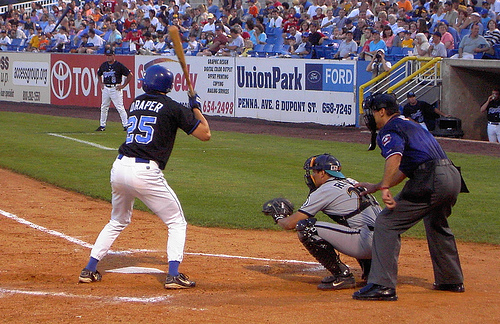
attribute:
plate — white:
[102, 259, 169, 282]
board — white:
[277, 31, 368, 135]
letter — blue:
[290, 74, 300, 91]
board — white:
[233, 55, 358, 126]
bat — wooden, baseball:
[147, 22, 227, 111]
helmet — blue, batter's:
[141, 64, 173, 94]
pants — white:
[89, 150, 201, 264]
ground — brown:
[2, 162, 499, 322]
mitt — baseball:
[256, 188, 293, 228]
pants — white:
[418, 122, 429, 132]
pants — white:
[487, 122, 499, 142]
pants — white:
[89, 152, 187, 262]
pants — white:
[99, 83, 129, 125]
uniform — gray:
[296, 175, 385, 259]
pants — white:
[54, 138, 239, 311]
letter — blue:
[244, 70, 251, 87]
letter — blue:
[271, 65, 280, 87]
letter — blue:
[279, 72, 288, 87]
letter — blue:
[286, 72, 294, 89]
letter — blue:
[291, 65, 303, 90]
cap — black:
[101, 47, 113, 54]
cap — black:
[407, 90, 414, 97]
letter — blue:
[267, 60, 284, 94]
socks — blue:
[76, 247, 181, 280]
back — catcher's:
[324, 176, 385, 262]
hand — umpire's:
[344, 179, 374, 199]